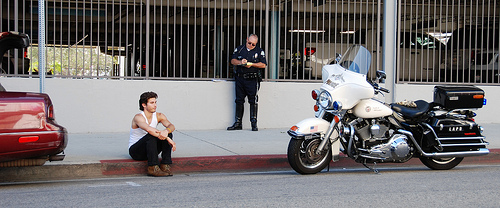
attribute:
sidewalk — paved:
[81, 112, 310, 161]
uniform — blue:
[228, 41, 268, 131]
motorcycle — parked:
[278, 33, 497, 188]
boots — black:
[224, 100, 265, 132]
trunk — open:
[1, 22, 51, 121]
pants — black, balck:
[122, 129, 181, 169]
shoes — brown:
[143, 162, 175, 179]